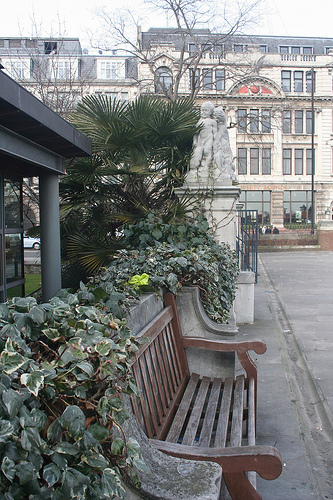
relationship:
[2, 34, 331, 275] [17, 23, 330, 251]
building has window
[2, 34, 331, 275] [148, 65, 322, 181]
building with windows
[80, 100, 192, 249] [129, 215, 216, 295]
plant with leaves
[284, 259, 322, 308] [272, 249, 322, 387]
patch of street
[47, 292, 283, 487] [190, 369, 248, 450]
bench has seat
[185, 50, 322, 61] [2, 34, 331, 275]
words at top of building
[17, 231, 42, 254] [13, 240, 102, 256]
car on street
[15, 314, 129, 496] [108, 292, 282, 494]
bushes behind bench